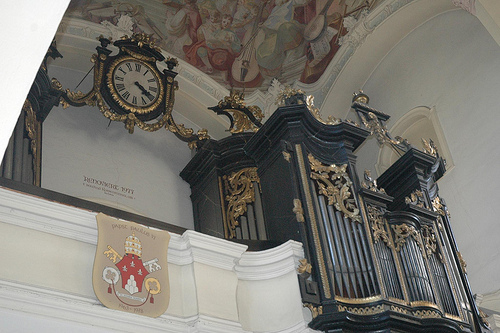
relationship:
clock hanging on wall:
[90, 27, 180, 134] [37, 35, 219, 234]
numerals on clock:
[112, 59, 142, 109] [105, 54, 164, 114]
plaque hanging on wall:
[93, 212, 176, 318] [0, 184, 322, 331]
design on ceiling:
[61, 0, 391, 98] [163, 21, 413, 131]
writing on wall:
[76, 171, 142, 203] [4, 113, 204, 226]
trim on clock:
[82, 29, 121, 82] [90, 30, 181, 134]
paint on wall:
[334, 10, 484, 290] [339, 17, 496, 314]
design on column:
[306, 151, 363, 228] [244, 109, 394, 331]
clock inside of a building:
[90, 30, 181, 134] [0, 2, 498, 332]